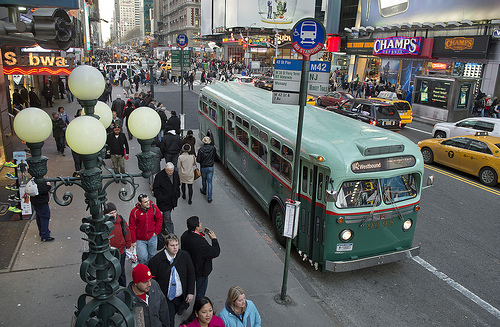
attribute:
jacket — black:
[149, 247, 195, 298]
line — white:
[410, 250, 497, 322]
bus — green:
[196, 80, 434, 273]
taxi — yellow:
[400, 125, 499, 204]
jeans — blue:
[197, 163, 214, 205]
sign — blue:
[289, 17, 328, 58]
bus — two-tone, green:
[230, 85, 404, 246]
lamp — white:
[10, 62, 160, 323]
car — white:
[431, 107, 498, 151]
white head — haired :
[164, 161, 174, 175]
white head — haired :
[201, 135, 211, 145]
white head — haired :
[115, 91, 121, 98]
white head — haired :
[487, 92, 491, 98]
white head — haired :
[128, 92, 133, 98]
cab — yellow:
[417, 128, 497, 181]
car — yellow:
[411, 127, 492, 169]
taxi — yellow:
[417, 127, 499, 183]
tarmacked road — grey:
[326, 284, 469, 325]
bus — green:
[199, 69, 444, 294]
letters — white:
[375, 39, 416, 51]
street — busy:
[106, 51, 440, 278]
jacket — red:
[127, 201, 161, 244]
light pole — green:
[20, 66, 161, 325]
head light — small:
[338, 223, 353, 243]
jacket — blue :
[222, 310, 263, 322]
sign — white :
[355, 157, 415, 173]